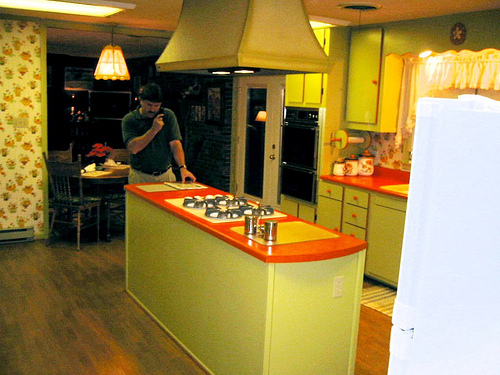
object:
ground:
[0, 231, 397, 372]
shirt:
[122, 105, 183, 172]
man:
[121, 83, 196, 184]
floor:
[0, 241, 208, 375]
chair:
[42, 151, 100, 251]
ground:
[320, 151, 351, 168]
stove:
[165, 194, 287, 223]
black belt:
[131, 164, 172, 175]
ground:
[416, 157, 441, 185]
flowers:
[86, 143, 113, 165]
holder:
[331, 131, 373, 150]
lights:
[255, 111, 266, 122]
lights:
[309, 21, 331, 29]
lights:
[212, 70, 255, 75]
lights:
[419, 51, 432, 58]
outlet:
[332, 276, 344, 298]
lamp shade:
[94, 43, 131, 81]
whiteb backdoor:
[231, 75, 284, 205]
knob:
[352, 195, 358, 218]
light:
[98, 49, 127, 75]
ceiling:
[0, 0, 498, 32]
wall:
[269, 264, 352, 373]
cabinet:
[346, 23, 415, 133]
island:
[123, 181, 367, 374]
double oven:
[280, 105, 323, 204]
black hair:
[139, 83, 166, 103]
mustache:
[147, 111, 155, 114]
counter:
[125, 181, 367, 257]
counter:
[319, 173, 409, 199]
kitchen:
[0, 0, 500, 375]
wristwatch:
[178, 164, 186, 170]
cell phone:
[159, 106, 165, 118]